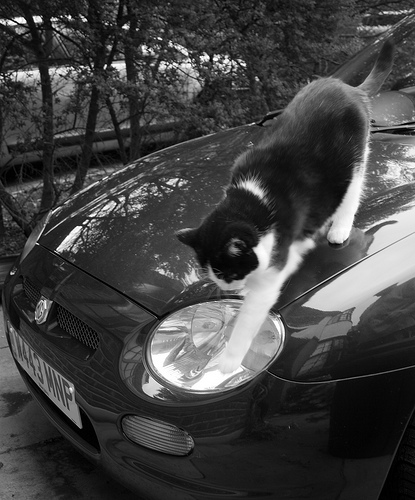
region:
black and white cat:
[194, 88, 387, 385]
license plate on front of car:
[3, 311, 99, 435]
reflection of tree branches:
[39, 150, 181, 267]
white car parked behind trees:
[6, 10, 247, 161]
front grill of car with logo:
[9, 263, 115, 359]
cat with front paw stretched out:
[169, 172, 330, 400]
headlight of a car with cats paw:
[136, 288, 306, 417]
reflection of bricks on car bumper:
[53, 349, 213, 437]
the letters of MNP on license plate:
[41, 351, 96, 434]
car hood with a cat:
[21, 61, 396, 383]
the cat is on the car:
[180, 37, 404, 374]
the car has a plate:
[5, 325, 90, 437]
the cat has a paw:
[205, 341, 255, 374]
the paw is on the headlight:
[218, 301, 250, 379]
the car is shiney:
[322, 262, 391, 324]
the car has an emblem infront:
[26, 288, 57, 327]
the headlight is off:
[143, 304, 287, 389]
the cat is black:
[152, 20, 399, 382]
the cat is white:
[166, 17, 392, 383]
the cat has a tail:
[364, 34, 396, 98]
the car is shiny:
[52, 217, 343, 495]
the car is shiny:
[130, 208, 245, 420]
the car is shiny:
[117, 185, 208, 488]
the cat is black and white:
[132, 54, 412, 283]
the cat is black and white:
[155, 83, 316, 327]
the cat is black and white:
[136, 106, 390, 405]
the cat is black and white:
[176, 136, 333, 262]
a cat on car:
[147, 148, 298, 458]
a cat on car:
[174, 187, 363, 385]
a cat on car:
[119, 161, 325, 348]